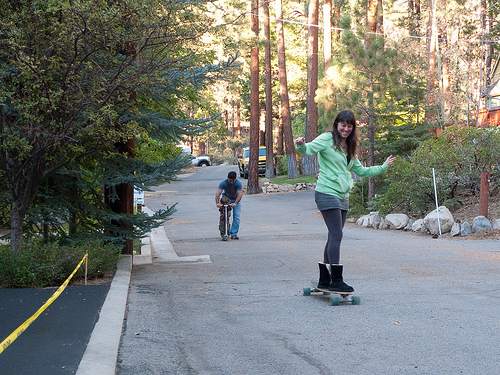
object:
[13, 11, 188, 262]
tree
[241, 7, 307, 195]
trunks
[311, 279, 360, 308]
skateboard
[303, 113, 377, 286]
woman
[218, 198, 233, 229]
kid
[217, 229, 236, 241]
scooter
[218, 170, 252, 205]
man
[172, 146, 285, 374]
street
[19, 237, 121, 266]
bush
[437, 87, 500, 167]
house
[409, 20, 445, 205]
side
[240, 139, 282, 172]
truck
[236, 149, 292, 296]
road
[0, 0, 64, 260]
trees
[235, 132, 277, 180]
car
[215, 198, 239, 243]
boy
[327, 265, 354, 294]
shoes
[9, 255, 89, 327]
rope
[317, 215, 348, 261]
pants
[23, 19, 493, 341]
picture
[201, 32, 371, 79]
daytime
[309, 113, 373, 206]
girl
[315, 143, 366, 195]
jacket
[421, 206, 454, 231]
rocks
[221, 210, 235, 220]
shirt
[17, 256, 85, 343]
tape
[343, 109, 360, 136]
hair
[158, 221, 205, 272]
marker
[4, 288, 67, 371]
driveway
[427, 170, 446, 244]
post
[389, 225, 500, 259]
ground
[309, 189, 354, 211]
skirt